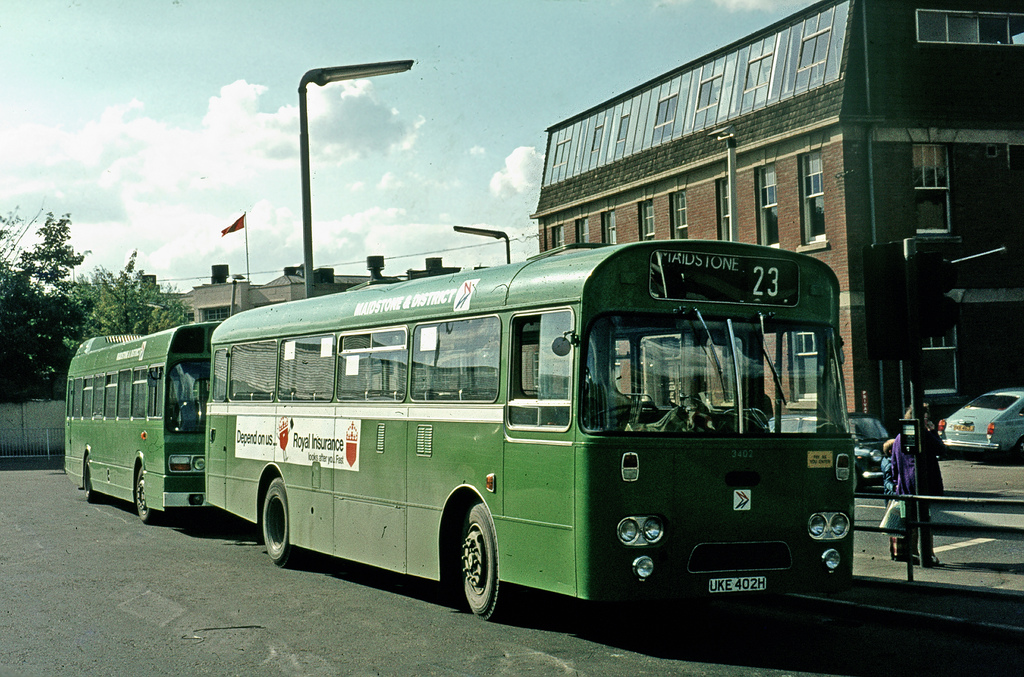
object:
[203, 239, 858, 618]
bus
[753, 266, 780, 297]
number 23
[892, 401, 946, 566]
person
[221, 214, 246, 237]
flag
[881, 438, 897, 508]
child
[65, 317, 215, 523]
city bus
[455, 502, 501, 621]
tire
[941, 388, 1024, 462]
car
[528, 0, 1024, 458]
building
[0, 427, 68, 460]
barricade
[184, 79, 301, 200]
clouds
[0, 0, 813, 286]
sky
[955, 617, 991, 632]
crack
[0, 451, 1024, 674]
road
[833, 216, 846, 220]
brick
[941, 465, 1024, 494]
parking lot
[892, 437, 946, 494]
purple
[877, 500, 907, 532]
bag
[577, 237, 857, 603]
flat-face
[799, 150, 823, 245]
window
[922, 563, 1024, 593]
sidewalk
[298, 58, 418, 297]
street lamp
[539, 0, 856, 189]
row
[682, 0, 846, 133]
windows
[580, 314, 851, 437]
windshield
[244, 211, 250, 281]
flag pole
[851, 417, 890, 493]
car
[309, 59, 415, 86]
light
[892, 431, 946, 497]
jacket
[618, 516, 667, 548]
headlights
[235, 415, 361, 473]
advertisement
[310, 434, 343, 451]
insurance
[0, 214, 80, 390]
tree